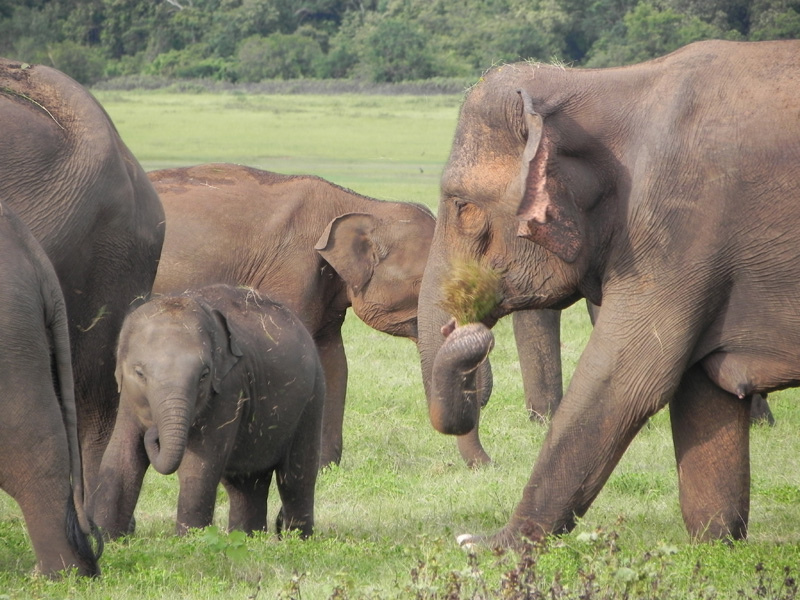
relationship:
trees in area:
[118, 3, 426, 81] [86, 3, 470, 107]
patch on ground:
[179, 533, 440, 597] [100, 515, 492, 596]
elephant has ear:
[132, 143, 446, 483] [307, 204, 391, 302]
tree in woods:
[211, 0, 280, 55] [4, 6, 798, 78]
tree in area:
[345, 9, 441, 84] [0, 0, 800, 84]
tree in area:
[426, 9, 574, 75] [0, 0, 800, 84]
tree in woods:
[132, 0, 236, 93] [4, 6, 798, 78]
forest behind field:
[10, 6, 798, 84] [118, 90, 455, 171]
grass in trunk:
[426, 314, 466, 337] [406, 309, 502, 442]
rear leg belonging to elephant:
[1, 359, 104, 581] [1, 205, 107, 580]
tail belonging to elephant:
[24, 234, 102, 568] [1, 205, 107, 580]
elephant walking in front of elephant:
[77, 276, 331, 542] [143, 163, 499, 474]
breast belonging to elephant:
[704, 350, 776, 399] [413, 32, 776, 558]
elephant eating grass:
[413, 32, 776, 558] [432, 248, 512, 335]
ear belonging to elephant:
[314, 212, 389, 297] [143, 163, 499, 474]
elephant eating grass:
[413, 32, 776, 558] [439, 251, 508, 326]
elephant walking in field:
[1, 205, 107, 580] [0, 90, 800, 600]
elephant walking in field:
[0, 59, 165, 581] [0, 90, 800, 600]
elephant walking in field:
[77, 276, 331, 542] [0, 90, 800, 600]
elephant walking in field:
[143, 163, 499, 474] [0, 90, 800, 600]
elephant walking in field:
[413, 32, 776, 558] [0, 90, 800, 600]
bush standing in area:
[357, 18, 428, 84] [0, 0, 800, 84]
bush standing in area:
[472, 13, 568, 75] [0, 0, 800, 84]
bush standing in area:
[583, 4, 738, 69] [0, 0, 800, 84]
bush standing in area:
[141, 50, 190, 80] [0, 0, 800, 84]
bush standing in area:
[165, 56, 236, 82] [0, 0, 800, 84]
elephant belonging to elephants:
[1, 205, 107, 580] [0, 38, 800, 585]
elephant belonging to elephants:
[0, 59, 165, 581] [0, 38, 800, 585]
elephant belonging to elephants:
[143, 163, 499, 474] [0, 38, 800, 585]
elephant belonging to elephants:
[77, 276, 331, 542] [0, 38, 800, 585]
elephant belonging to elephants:
[413, 32, 776, 558] [0, 38, 800, 585]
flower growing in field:
[455, 529, 478, 568] [0, 90, 800, 600]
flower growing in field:
[573, 528, 600, 544] [0, 90, 800, 600]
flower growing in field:
[653, 535, 683, 559] [0, 90, 800, 600]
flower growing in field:
[615, 562, 639, 583] [0, 90, 800, 600]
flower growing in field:
[688, 554, 702, 584] [0, 90, 800, 600]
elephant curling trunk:
[413, 32, 776, 558] [411, 248, 496, 438]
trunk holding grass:
[411, 248, 496, 438] [432, 254, 512, 326]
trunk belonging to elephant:
[411, 248, 496, 438] [413, 32, 776, 558]